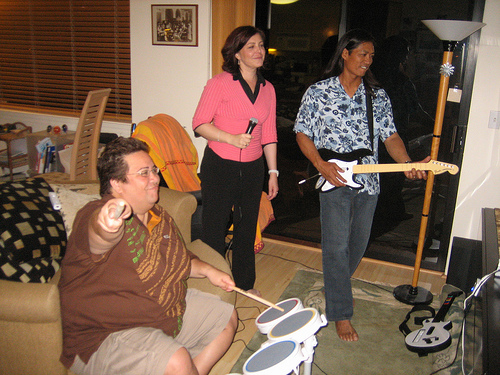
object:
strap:
[365, 82, 375, 150]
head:
[95, 136, 160, 211]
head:
[229, 25, 266, 68]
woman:
[191, 24, 279, 299]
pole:
[408, 49, 456, 295]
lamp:
[419, 19, 487, 41]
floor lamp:
[394, 17, 489, 308]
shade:
[472, 28, 482, 41]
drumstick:
[232, 286, 284, 312]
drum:
[253, 297, 328, 342]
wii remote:
[48, 191, 62, 211]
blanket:
[131, 113, 203, 195]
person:
[55, 137, 239, 375]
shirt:
[292, 75, 397, 196]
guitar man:
[292, 27, 432, 341]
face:
[346, 42, 375, 76]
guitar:
[297, 148, 460, 196]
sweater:
[192, 70, 279, 163]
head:
[338, 31, 378, 78]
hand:
[314, 159, 348, 187]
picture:
[149, 3, 198, 47]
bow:
[439, 62, 454, 78]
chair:
[0, 180, 236, 375]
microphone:
[245, 117, 259, 134]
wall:
[134, 47, 198, 114]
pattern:
[315, 107, 372, 149]